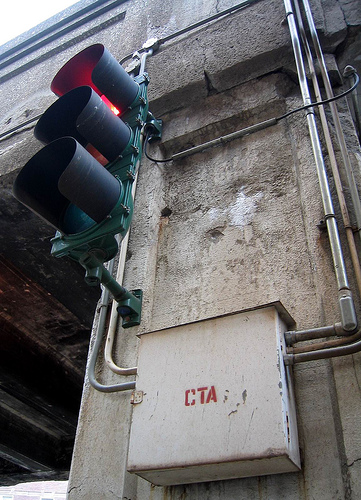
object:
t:
[196, 385, 206, 404]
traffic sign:
[11, 47, 162, 328]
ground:
[293, 76, 329, 114]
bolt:
[133, 117, 145, 126]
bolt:
[137, 97, 147, 106]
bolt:
[129, 143, 140, 156]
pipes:
[78, 0, 359, 392]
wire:
[284, 5, 359, 252]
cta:
[184, 384, 218, 406]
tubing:
[74, 275, 142, 395]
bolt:
[125, 168, 138, 182]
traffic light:
[50, 42, 143, 111]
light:
[12, 42, 140, 237]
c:
[185, 387, 197, 407]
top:
[11, 41, 148, 264]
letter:
[184, 388, 197, 406]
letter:
[196, 385, 208, 403]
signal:
[15, 45, 165, 266]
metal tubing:
[129, 2, 254, 52]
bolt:
[119, 199, 131, 220]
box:
[8, 43, 150, 260]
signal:
[12, 137, 133, 229]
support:
[82, 251, 145, 330]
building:
[0, 0, 359, 498]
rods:
[291, 35, 341, 276]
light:
[50, 42, 140, 116]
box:
[125, 298, 303, 487]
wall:
[139, 2, 359, 496]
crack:
[203, 66, 219, 100]